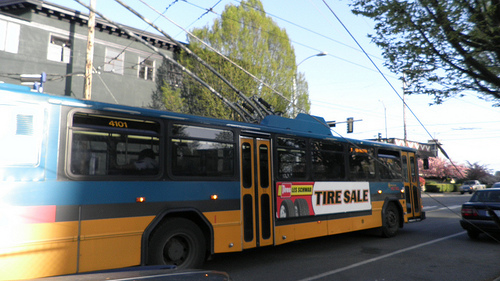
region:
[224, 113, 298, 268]
Yellow doors on bus.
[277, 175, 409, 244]
Tire sign on side of bus.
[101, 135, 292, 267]
Bus is blue and yellow.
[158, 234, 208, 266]
Bus has black tire.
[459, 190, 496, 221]
Car on street near bus.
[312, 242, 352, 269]
White line on road.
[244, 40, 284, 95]
Green leaves on trees.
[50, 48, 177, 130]
Gray building on left side of bus.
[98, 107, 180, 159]
4101 on side of bus.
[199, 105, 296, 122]
Top of bus is blue.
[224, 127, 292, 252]
a couple of doors on a bus.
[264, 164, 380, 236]
A sign on the side of a bus.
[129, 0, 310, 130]
a tall leaf filled tree.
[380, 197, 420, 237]
a wheel on a bus.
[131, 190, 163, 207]
a light on a bus.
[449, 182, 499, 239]
a parked car on a road.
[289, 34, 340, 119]
a street light near a street.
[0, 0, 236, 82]
a tall multi story building.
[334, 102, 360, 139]
a traffic signal.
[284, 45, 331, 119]
a tall light.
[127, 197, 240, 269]
the tires on bus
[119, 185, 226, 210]
lights on the bus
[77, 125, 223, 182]
windows on the bus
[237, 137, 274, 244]
the door is orange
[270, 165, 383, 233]
the advertisment is white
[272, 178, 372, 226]
advertisement on the bus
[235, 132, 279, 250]
door is on the bus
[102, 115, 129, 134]
the lettering is orange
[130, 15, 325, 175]
wires above the bus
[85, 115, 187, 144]
lettering on the screen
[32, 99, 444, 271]
the bus is yellow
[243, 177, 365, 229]
a tire advertisement on the side of the bus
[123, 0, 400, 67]
wires above the bus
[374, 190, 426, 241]
the tires are black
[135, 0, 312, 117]
a bushy green tree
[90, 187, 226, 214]
lights on the side of the bus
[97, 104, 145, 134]
the number 4101 on the side of the bus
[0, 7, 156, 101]
grey building to the left of the bus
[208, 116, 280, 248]
the bus doors are yellow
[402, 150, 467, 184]
pink trees ahead of the bus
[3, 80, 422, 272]
Yellow and blue bus moving down street.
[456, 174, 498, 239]
Rear of car parked in parking space.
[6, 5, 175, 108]
Top of gray building next to street.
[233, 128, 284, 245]
Rear passenger doors on bus.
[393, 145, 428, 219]
Front passenger doors on bus.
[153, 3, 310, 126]
Top of tree growing on sidewalk next to gray building.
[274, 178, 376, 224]
Advertising sign on side of bus.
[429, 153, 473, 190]
Tree with pink blooming flowers.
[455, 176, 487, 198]
Pick up truck moving in traffic.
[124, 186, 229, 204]
Lights on side of bus.